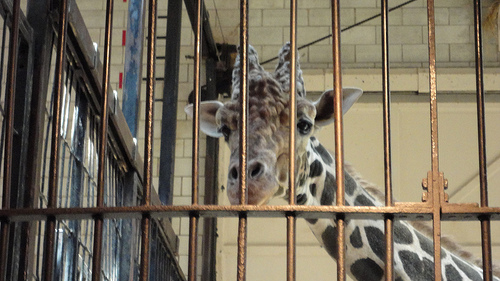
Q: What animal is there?
A: Giraffe.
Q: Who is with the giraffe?
A: No one.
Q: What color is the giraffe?
A: Brown.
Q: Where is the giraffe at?
A: Zoo.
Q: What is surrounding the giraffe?
A: Gate.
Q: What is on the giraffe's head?
A: Horns.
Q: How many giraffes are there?
A: One.